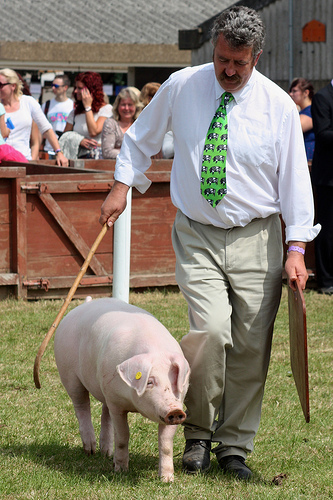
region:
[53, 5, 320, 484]
A man and a pink pig.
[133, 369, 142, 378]
A yellow tag on the pig's ear.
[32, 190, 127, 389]
Brown wooden stick in the man's hand.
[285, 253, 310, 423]
Brown board in the man's right hand.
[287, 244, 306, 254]
A purple wristband.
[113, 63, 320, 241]
A white shirt with rolled up sleeves.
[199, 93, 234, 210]
Pig designs on a green necktie.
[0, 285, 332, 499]
Grass on the ground.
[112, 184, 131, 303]
White pole behind the pig.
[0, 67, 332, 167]
Spectators in the background.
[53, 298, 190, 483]
the pig on the grass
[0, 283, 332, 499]
the grass covering the ground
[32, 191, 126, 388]
the wooden stick in the man's hand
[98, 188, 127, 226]
the man's hand holding the stick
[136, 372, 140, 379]
the yellow tag in the man's ear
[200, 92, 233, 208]
the green tie around the man's neck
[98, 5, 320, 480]
the man walking on the grass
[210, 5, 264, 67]
the hair on the man's head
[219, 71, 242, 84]
the mustache on the man's face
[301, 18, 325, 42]
the orange object on the building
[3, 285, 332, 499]
Pink walking in grass.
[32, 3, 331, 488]
Man with rod in hand standing beside pig.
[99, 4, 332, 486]
Man with white long sleeve shirt.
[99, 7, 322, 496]
Man wearing decorated green neck tie.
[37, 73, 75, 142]
Man with blue lensed shades looking away.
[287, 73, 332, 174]
Lady in short sleeve blue shirt.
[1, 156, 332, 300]
Wooden fence with bolts.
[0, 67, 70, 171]
Lady with white and blue shirt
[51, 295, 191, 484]
Pig with 2 floppy ears.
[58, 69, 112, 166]
Lady with red hair holding sweater over her arm.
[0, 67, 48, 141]
this is a person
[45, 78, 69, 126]
this is a person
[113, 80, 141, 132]
this is a person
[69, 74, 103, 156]
this is a person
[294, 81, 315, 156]
this is a person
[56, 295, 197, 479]
this is a pig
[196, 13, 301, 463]
this is a person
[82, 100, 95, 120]
the person is wearing a watch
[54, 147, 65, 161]
the person is wearing a watch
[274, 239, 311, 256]
the person is wearing a watch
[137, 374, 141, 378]
A yellow tag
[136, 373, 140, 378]
A tag on the ear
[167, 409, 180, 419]
The snout of a pig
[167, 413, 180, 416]
The nostrils of a pig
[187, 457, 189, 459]
Dirt on the shoe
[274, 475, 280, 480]
A lump of soil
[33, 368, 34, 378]
The crook of a stick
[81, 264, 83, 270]
A stick extended out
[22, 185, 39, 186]
A latch on the gate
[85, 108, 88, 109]
A watch on the wrist